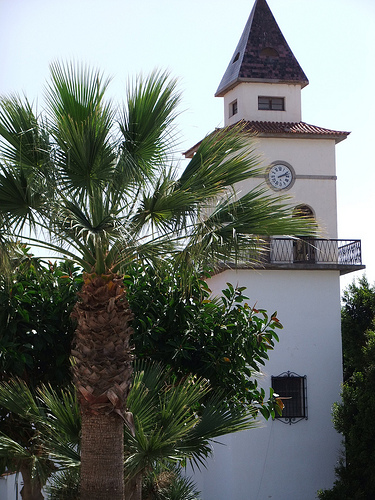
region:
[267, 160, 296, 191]
a round white clock face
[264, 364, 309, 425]
a window on the building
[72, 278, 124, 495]
a brown tree trunk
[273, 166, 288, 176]
the hands of a clock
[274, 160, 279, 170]
a number on the clock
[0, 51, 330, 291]
a green leafy tree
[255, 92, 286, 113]
a window on the tower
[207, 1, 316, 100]
the roof of the tower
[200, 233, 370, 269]
a balcony on the tower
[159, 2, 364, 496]
a white clock tower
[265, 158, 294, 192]
Roman numeral clock on wall.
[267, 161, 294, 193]
Round clock on wall.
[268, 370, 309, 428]
Small square window with bars.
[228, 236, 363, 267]
Black wrought iron gate.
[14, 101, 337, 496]
Tall green palm tree.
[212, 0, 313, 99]
Pointed roof with window.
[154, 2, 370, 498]
Tall white building with pointed roof.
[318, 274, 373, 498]
Bushy green trees next to building.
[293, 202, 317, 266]
Rounded topped door to balcony,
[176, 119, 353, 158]
Red shingled roof to building.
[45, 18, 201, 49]
this is the sky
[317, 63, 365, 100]
the sky is blue in color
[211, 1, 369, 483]
this is a building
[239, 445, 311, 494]
the building is white in color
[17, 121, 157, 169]
these are some leaves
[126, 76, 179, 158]
the leaves are thin and long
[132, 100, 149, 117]
the leaves are green in color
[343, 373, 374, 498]
this is a hedge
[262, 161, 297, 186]
this is a clock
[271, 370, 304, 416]
this is a window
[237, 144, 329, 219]
the clock is white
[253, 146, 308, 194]
the numbers are roman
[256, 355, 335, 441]
wrought iron window bars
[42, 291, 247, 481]
these are palm trees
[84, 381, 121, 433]
palm bark is crosshatched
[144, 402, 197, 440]
palm fronds are green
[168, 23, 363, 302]
the clock tower is white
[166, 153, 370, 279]
the balcony on a clock tower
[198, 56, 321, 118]
two windows up top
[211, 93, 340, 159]
the tiles on the roof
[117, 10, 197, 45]
the sky is blue in color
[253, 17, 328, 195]
this is a building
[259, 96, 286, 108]
this is a window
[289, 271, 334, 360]
this is the wall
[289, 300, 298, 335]
the wall is white in color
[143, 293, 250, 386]
this is a tree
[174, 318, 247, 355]
the leaves are green in color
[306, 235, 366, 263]
this is the balcony